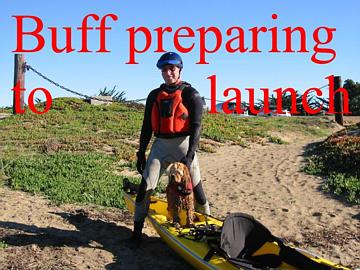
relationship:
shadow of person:
[0, 212, 93, 249] [122, 51, 214, 251]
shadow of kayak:
[46, 210, 170, 269] [119, 185, 345, 268]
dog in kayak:
[164, 161, 202, 228] [119, 185, 345, 268]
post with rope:
[11, 52, 31, 114] [23, 62, 152, 107]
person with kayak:
[122, 51, 214, 251] [119, 185, 345, 268]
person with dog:
[122, 51, 214, 251] [164, 161, 202, 228]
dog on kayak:
[164, 161, 202, 228] [119, 185, 345, 268]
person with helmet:
[122, 51, 214, 251] [156, 51, 185, 69]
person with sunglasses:
[122, 51, 214, 251] [157, 64, 178, 72]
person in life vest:
[122, 51, 214, 251] [151, 87, 192, 133]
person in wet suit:
[122, 51, 214, 251] [129, 84, 214, 228]